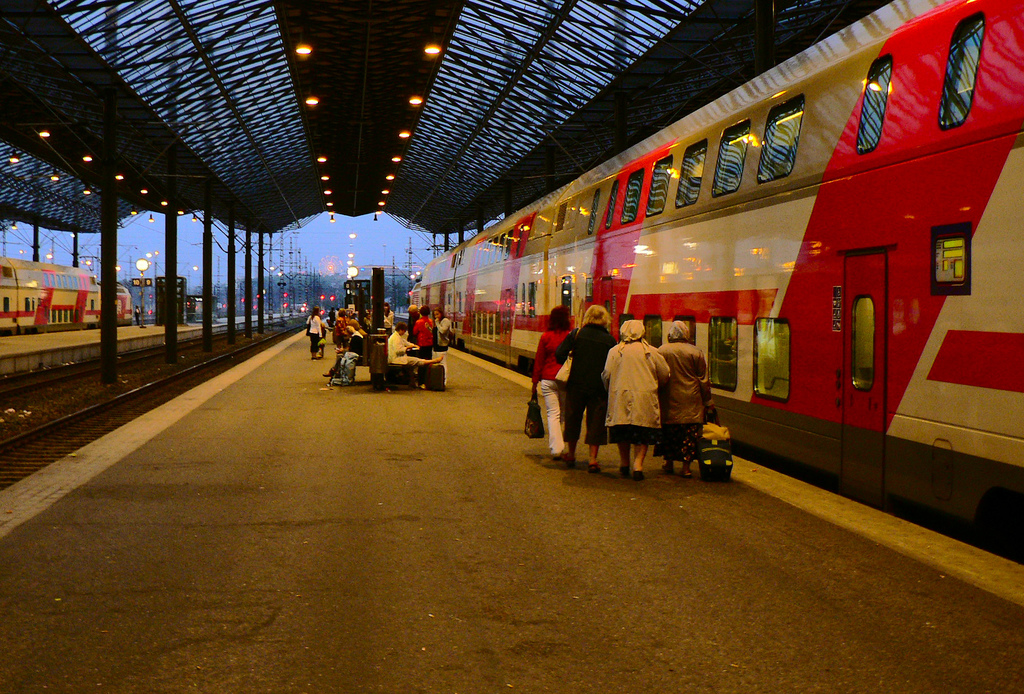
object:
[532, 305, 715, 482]
old women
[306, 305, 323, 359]
person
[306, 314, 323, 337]
shirt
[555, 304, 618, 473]
woman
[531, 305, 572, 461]
woman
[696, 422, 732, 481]
luggage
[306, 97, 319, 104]
light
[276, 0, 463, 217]
ceiling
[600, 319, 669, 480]
lady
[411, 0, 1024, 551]
train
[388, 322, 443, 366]
person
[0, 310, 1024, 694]
platform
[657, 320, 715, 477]
lady